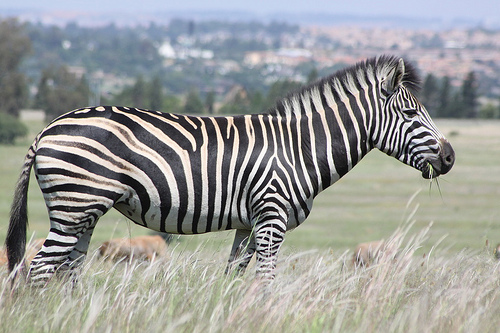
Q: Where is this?
A: This is at the field.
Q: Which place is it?
A: It is a field.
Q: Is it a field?
A: Yes, it is a field.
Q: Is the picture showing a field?
A: Yes, it is showing a field.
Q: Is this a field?
A: Yes, it is a field.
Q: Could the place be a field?
A: Yes, it is a field.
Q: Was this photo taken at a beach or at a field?
A: It was taken at a field.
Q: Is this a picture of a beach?
A: No, the picture is showing a field.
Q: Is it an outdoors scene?
A: Yes, it is outdoors.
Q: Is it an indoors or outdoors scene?
A: It is outdoors.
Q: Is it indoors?
A: No, it is outdoors.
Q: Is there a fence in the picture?
A: No, there are no fences.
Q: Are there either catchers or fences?
A: No, there are no fences or catchers.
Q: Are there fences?
A: No, there are no fences.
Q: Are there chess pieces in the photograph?
A: No, there are no chess pieces.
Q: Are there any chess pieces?
A: No, there are no chess pieces.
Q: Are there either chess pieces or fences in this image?
A: No, there are no chess pieces or fences.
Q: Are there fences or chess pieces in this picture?
A: No, there are no chess pieces or fences.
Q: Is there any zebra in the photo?
A: Yes, there is a zebra.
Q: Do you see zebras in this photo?
A: Yes, there is a zebra.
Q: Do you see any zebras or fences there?
A: Yes, there is a zebra.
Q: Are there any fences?
A: No, there are no fences.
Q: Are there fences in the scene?
A: No, there are no fences.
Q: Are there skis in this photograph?
A: No, there are no skis.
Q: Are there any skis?
A: No, there are no skis.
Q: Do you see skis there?
A: No, there are no skis.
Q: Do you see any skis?
A: No, there are no skis.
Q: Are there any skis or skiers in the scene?
A: No, there are no skis or skiers.